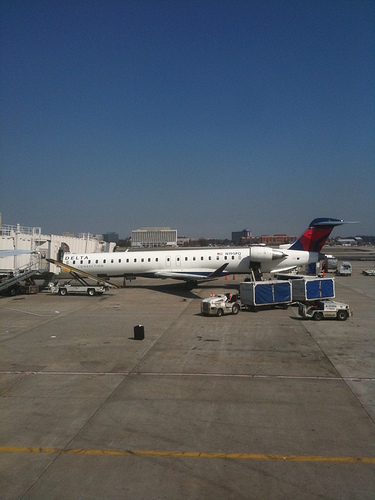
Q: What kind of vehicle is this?
A: Plane.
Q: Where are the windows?
A: On the jet.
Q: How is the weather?
A: Clear.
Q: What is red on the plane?
A: The tail of the plane.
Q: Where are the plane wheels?
A: Under the plane.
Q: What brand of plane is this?
A: DELTA.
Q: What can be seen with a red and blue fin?
A: The body of an airplane.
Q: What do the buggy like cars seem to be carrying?
A: Luggage inside of bins.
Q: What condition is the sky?
A: Blue without clouds.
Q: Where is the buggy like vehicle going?
A: To the airport.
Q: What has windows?
A: The airplane.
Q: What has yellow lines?
A: The pavement.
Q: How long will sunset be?
A: Couple hours.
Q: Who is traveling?
A: Airline passengers.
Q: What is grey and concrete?
A: Runway.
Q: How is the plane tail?
A: Red and white.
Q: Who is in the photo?
A: Nobody.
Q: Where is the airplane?
A: At the gate.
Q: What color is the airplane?
A: White.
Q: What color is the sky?
A: Blue.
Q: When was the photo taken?
A: Daytime.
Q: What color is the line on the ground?
A: Yellow.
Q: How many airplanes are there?
A: One.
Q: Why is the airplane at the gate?
A: To meet the passengers.